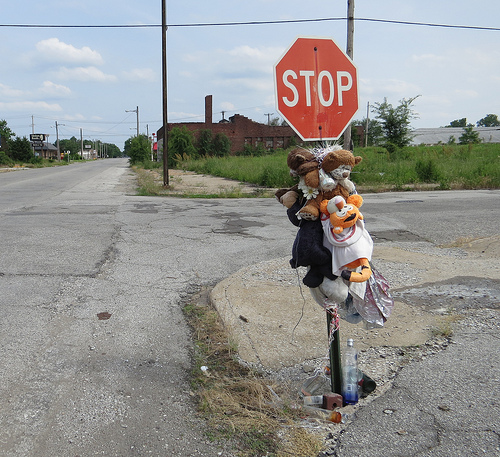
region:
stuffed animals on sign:
[281, 149, 369, 317]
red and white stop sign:
[264, 36, 345, 138]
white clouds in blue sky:
[10, 25, 45, 77]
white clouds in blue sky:
[18, 48, 58, 110]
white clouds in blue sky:
[47, 5, 97, 59]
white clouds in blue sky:
[41, 51, 96, 88]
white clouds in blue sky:
[185, 21, 225, 83]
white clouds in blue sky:
[217, 15, 257, 73]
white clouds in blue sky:
[371, 23, 406, 78]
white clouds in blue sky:
[422, 45, 496, 97]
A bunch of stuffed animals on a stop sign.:
[259, 136, 415, 330]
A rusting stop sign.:
[241, 23, 381, 153]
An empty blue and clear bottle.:
[336, 333, 369, 419]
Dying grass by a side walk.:
[163, 276, 321, 452]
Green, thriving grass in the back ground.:
[221, 155, 269, 177]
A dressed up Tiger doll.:
[311, 190, 376, 285]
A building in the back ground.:
[148, 93, 282, 160]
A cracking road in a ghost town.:
[44, 197, 159, 343]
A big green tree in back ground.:
[359, 90, 426, 166]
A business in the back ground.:
[27, 125, 74, 171]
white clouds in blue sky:
[18, 46, 86, 84]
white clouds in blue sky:
[74, 45, 122, 85]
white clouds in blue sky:
[68, 78, 118, 116]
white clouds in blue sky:
[188, 39, 236, 76]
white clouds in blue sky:
[368, 45, 439, 97]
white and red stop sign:
[272, 26, 372, 143]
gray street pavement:
[28, 211, 86, 282]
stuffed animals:
[320, 186, 372, 266]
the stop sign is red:
[273, 35, 363, 144]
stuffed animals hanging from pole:
[281, 145, 391, 327]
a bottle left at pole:
[346, 333, 361, 403]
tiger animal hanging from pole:
[321, 188, 373, 283]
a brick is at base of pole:
[324, 392, 346, 407]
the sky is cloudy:
[0, 0, 498, 147]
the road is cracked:
[0, 196, 207, 453]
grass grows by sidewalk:
[186, 285, 316, 452]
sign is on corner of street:
[276, 35, 357, 404]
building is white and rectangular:
[399, 124, 499, 149]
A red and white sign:
[273, 35, 360, 140]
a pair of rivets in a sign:
[310, 43, 324, 130]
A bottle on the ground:
[341, 335, 359, 402]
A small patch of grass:
[178, 298, 322, 455]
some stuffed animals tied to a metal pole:
[276, 143, 374, 305]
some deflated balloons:
[305, 261, 397, 378]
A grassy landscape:
[180, 144, 498, 187]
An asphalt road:
[0, 156, 499, 453]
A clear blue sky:
[0, 0, 498, 150]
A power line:
[0, 16, 498, 43]